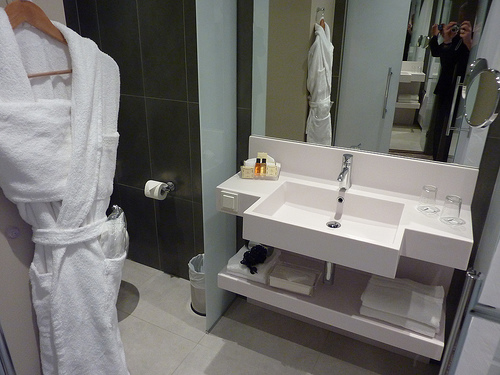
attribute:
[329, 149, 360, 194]
fixture — silver , sink 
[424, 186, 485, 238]
cup — plastic 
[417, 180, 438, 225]
glass — clear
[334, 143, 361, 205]
sink faucet — gray 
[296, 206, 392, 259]
ground — clean 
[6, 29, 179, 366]
robe — white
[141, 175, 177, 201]
paper — white 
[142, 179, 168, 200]
toilet paper — white 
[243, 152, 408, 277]
sink — white , large 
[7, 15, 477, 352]
bathroom — fancy , modern 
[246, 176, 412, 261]
sink — white 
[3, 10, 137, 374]
white bathrobe — white 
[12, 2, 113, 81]
hanger — wooden 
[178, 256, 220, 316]
trashcan — small 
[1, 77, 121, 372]
robe — white 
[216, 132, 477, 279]
sink — white 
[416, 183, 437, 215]
glass — empty , upside down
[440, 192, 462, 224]
glass — empty , upside down